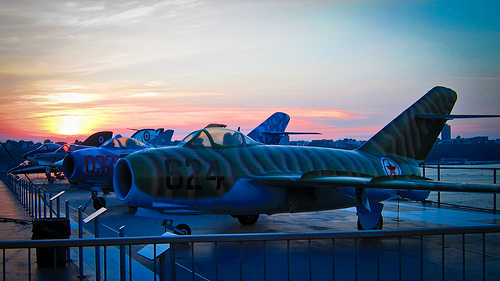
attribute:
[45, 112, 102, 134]
sun — setting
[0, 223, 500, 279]
fence — metal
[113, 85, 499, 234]
airplane — parked, green, striped, painted, vintage, old, jet, military jet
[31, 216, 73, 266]
garbage can — for visitors, dark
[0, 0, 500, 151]
sky — dark, yellow, orange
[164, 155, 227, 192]
number — 624, identification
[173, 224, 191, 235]
front wheel — down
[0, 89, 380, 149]
clouds — pink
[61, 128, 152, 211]
airplane — parked, patterned, camoflauge, vintage, military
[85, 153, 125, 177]
number — identification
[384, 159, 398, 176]
star — red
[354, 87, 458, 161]
tail — striped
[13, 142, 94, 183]
airplane — parked, vintage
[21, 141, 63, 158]
airplane — parked, vintage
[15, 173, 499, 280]
concrete — wet